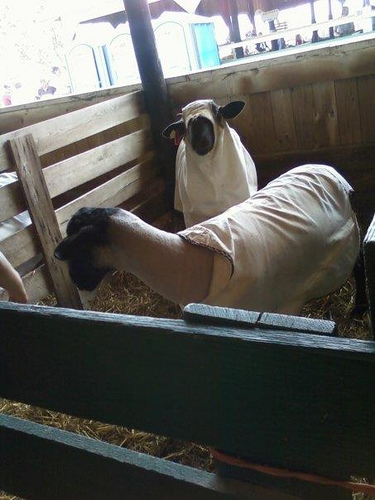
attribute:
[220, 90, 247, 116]
ear — sticking out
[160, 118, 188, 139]
ear — sticking out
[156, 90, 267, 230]
sheep — covered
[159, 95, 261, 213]
sheep — fenced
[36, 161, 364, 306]
sheep — fenced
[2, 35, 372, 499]
enclosure — brown, wooden, post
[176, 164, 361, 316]
tarp — white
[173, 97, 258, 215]
tarp — white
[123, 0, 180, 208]
pole — tall, black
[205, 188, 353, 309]
cloth — white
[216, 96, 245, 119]
ear — back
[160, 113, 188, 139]
ear — back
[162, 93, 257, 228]
sheep — covered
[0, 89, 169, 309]
fence — wooden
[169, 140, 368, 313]
covering — white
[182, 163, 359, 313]
covering — white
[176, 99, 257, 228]
covering — white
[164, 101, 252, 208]
sheep — covered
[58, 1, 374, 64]
building — in background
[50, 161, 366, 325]
sheep — covered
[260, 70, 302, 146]
plank — horizontal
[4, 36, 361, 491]
fences — wooden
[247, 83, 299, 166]
plank — vertical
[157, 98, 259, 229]
sheep — covered